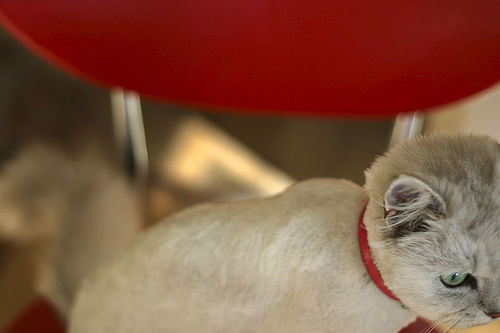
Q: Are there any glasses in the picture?
A: No, there are no glasses.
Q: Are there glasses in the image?
A: No, there are no glasses.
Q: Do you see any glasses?
A: No, there are no glasses.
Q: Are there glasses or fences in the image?
A: No, there are no glasses or fences.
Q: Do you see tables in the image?
A: Yes, there is a table.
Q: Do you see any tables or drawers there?
A: Yes, there is a table.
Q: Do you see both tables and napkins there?
A: No, there is a table but no napkins.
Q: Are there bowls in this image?
A: No, there are no bowls.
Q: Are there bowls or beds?
A: No, there are no bowls or beds.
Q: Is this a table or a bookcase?
A: This is a table.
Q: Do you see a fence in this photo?
A: No, there are no fences.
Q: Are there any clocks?
A: No, there are no clocks.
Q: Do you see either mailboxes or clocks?
A: No, there are no clocks or mailboxes.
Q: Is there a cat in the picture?
A: Yes, there is a cat.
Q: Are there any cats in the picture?
A: Yes, there is a cat.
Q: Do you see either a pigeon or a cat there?
A: Yes, there is a cat.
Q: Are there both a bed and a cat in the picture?
A: No, there is a cat but no beds.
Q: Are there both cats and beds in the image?
A: No, there is a cat but no beds.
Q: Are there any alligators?
A: No, there are no alligators.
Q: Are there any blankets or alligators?
A: No, there are no alligators or blankets.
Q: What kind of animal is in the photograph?
A: The animal is a cat.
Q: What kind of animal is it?
A: The animal is a cat.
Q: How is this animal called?
A: This is a cat.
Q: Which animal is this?
A: This is a cat.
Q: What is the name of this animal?
A: This is a cat.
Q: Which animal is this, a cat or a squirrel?
A: This is a cat.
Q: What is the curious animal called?
A: The animal is a cat.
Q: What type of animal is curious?
A: The animal is a cat.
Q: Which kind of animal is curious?
A: The animal is a cat.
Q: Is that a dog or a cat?
A: That is a cat.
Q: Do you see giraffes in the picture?
A: No, there are no giraffes.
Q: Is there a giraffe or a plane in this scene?
A: No, there are no giraffes or airplanes.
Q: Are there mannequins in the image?
A: No, there are no mannequins.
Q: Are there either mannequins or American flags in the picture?
A: No, there are no mannequins or American flags.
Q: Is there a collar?
A: Yes, there is a collar.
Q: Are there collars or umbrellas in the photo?
A: Yes, there is a collar.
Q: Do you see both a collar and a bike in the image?
A: No, there is a collar but no bikes.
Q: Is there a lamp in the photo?
A: No, there are no lamps.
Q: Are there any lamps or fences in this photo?
A: No, there are no lamps or fences.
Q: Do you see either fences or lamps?
A: No, there are no lamps or fences.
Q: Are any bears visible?
A: No, there are no bears.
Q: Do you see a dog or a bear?
A: No, there are no bears or dogs.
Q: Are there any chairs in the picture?
A: Yes, there is a chair.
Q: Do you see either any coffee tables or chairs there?
A: Yes, there is a chair.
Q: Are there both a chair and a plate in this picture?
A: No, there is a chair but no plates.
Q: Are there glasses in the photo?
A: No, there are no glasses.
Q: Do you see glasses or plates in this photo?
A: No, there are no glasses or plates.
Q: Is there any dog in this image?
A: No, there are no dogs.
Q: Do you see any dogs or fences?
A: No, there are no dogs or fences.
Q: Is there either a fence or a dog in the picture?
A: No, there are no dogs or fences.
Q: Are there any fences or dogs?
A: No, there are no dogs or fences.